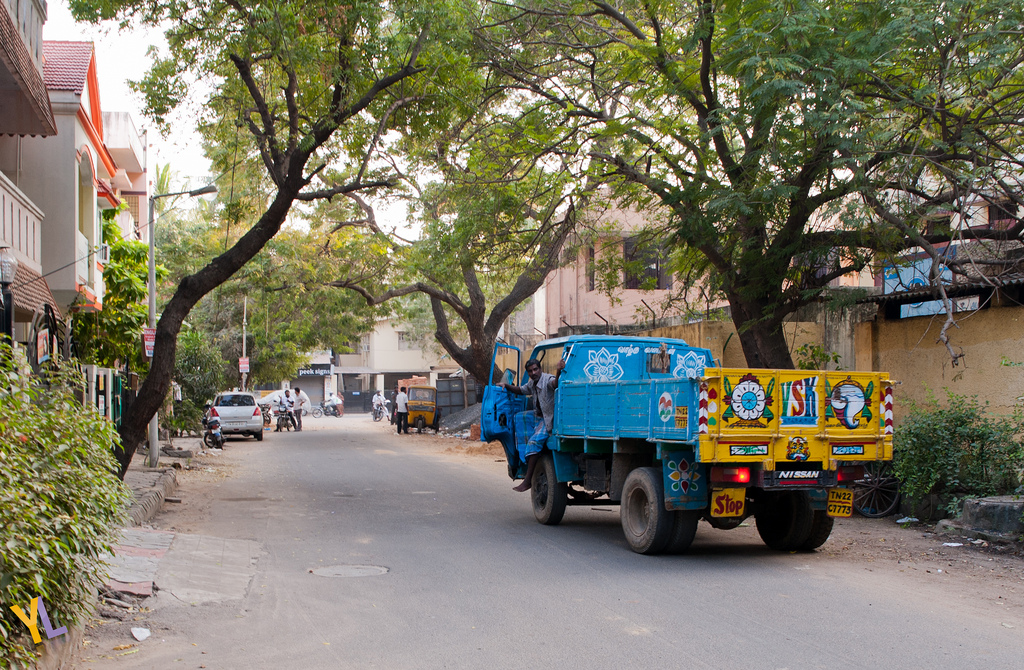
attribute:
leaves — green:
[631, 52, 964, 303]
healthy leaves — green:
[631, 52, 964, 303]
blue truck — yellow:
[448, 319, 945, 558]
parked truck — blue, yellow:
[448, 319, 945, 558]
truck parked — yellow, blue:
[461, 320, 905, 561]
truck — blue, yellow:
[474, 333, 930, 518]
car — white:
[201, 390, 288, 442]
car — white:
[199, 374, 279, 438]